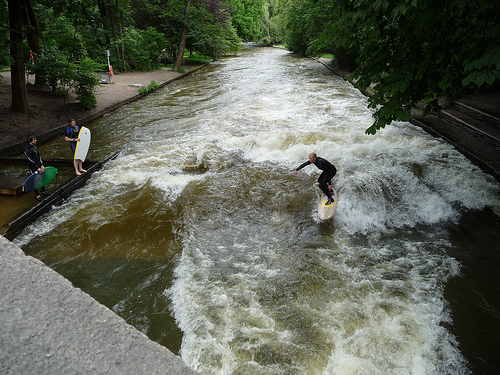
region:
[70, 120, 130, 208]
Person holding white board.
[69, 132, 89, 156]
Yellow edging on board.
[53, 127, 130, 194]
Person wearing blue and black wet suit.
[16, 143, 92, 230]
Person holding green and blue board.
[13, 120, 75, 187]
Person has dark hair.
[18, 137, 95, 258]
Person wearing black wet suit.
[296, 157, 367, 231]
Person wearing black wet suit.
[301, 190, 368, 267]
Person standing on surfboard.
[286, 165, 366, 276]
Person in water on board.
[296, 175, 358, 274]
Surfboard is white in color.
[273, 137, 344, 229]
A man is surfboarding on water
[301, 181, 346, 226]
Man's surfboard is gray in color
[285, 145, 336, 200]
Man is wearing a black wetsuit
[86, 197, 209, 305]
The water is brown in color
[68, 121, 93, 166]
Person is holding a white surfboard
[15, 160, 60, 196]
Man is holding a green and blue surfboard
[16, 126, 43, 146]
Person has dark colored hair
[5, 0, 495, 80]
Trees are in the background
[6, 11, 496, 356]
Photo was taken in the daytime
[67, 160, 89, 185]
Person on the right is barefoot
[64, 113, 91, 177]
Person holding a waterboard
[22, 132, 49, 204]
Boy in a black wetsuit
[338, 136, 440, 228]
White water waves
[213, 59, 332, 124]
Streaming water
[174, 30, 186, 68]
A brown tree trunck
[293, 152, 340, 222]
Man surfing the waves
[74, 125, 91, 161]
A grey colored waterboard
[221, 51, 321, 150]
A body of fast flowing water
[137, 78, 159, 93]
Patch of tall grass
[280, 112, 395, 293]
the man is surfing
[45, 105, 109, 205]
the woman is holding a surfboard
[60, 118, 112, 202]
the surfboard is white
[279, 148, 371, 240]
the man is wearing a wetsuit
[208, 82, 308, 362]
the water is brown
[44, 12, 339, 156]
trees on the side of the river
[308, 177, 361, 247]
the surfboard is brown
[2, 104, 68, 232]
a boy is standing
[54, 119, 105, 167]
the wet suit is blue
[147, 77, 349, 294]
the water is wavy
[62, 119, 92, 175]
A man in a wetsuit holding a boogie board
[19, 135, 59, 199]
A man in a wetsuit holding a surfboard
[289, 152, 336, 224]
A man on a surfboard surfing in a river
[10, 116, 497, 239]
White water breaking in a river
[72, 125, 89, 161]
A yellow and white boogie board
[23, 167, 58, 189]
A green and black surfboard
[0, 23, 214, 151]
Shoreline next to a rapidly moving river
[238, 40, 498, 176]
A path along a river bank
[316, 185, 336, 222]
A yellow and tan surfboard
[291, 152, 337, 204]
A surfer in a black wetsuit